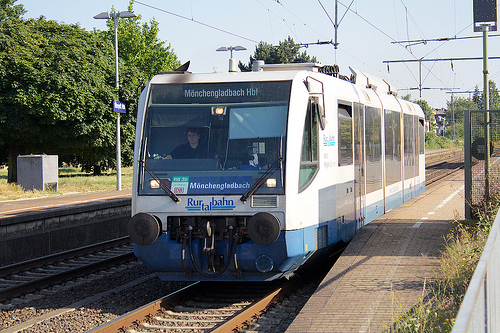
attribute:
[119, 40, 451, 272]
train — blue, white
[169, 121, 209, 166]
engineer — train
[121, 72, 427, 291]
train — white, blue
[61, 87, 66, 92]
leaves — green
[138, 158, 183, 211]
wipers — black, windshield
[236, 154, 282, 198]
wipers — black, windshield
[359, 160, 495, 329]
line — white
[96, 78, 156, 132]
sign — blue , white 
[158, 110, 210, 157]
shirt — black 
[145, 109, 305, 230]
wipers — black 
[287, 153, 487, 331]
walkway — brick 